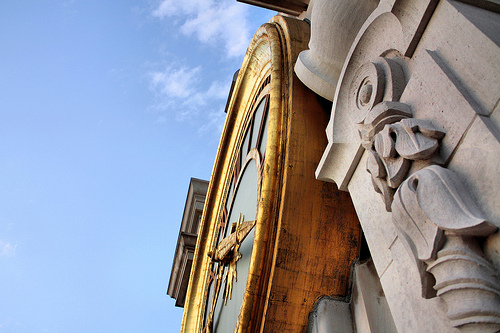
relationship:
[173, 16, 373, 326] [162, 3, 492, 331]
clock on building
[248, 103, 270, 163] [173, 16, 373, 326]
number on clock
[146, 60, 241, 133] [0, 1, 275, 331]
cloud in sky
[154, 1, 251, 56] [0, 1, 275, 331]
cloud in sky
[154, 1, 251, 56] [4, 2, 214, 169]
cloud in sky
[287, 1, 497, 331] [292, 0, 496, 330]
design on side of building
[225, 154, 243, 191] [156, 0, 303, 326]
number of clock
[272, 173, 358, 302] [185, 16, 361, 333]
side of clock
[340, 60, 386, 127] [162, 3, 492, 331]
design on building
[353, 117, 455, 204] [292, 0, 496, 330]
wave design on side of building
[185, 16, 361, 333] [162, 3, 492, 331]
clock on building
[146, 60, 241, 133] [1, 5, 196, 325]
cloud in sky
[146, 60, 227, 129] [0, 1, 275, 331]
cloud in sky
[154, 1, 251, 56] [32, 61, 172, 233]
cloud in sky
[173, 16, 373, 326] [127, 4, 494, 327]
clock on side of building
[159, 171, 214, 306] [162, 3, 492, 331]
roof of building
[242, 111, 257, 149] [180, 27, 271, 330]
gold line on face